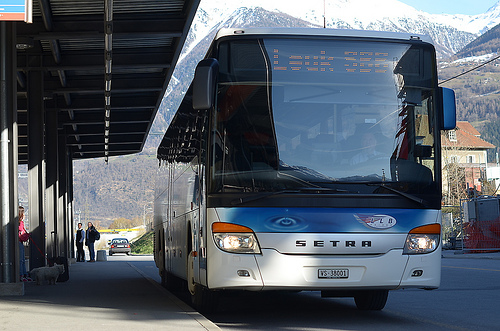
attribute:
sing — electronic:
[268, 42, 395, 78]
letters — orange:
[268, 47, 390, 79]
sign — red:
[250, 31, 422, 88]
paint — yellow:
[440, 261, 498, 275]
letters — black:
[320, 269, 328, 277]